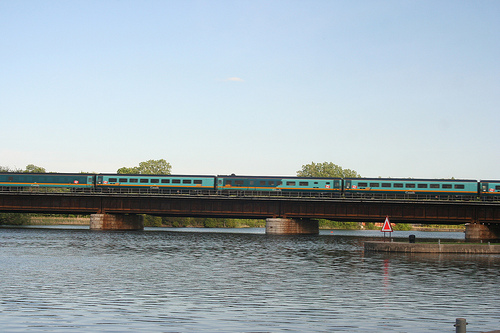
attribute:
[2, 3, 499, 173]
sky — clear, blue,  blue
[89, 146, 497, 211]
train — green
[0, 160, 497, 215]
train — passenger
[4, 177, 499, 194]
train — passenger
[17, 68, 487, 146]
clouds — white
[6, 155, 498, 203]
train — passenger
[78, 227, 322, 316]
water — calm, dark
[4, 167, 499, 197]
train — passenger train, passenger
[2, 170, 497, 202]
train — passenger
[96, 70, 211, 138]
clouds — white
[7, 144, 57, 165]
clouds —  white